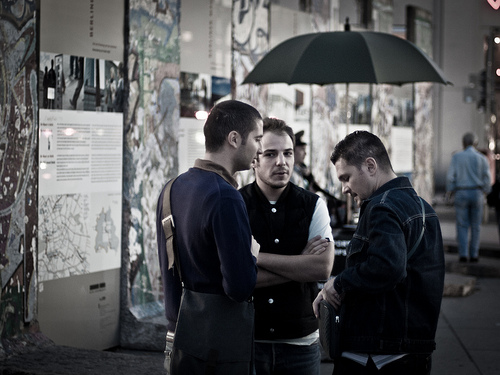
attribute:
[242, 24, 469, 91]
umbrella — black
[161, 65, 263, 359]
man — talking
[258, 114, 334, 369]
man — talking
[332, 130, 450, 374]
man — talking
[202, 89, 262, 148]
hair — black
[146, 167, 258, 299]
sweater — blue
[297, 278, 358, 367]
bag — black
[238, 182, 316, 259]
vest — black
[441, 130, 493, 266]
person — walking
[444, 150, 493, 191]
shirt — blue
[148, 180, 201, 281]
strap — brown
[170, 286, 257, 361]
bag — black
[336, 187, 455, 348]
jacket — denim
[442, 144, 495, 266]
clothing — blue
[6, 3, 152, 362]
wall — white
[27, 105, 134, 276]
picture — white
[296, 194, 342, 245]
shirt — white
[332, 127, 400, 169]
hair — brown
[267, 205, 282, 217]
button — white